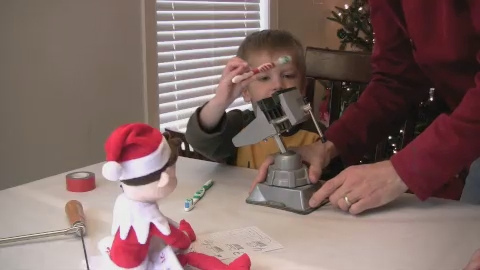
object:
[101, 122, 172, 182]
hat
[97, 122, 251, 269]
elf doll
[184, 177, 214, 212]
toothbrush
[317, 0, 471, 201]
christmas tree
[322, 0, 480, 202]
blouse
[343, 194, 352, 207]
wedding band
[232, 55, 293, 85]
toothbrush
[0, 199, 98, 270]
hack saw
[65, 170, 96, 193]
roll of tape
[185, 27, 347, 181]
boy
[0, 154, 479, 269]
table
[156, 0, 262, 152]
blinds